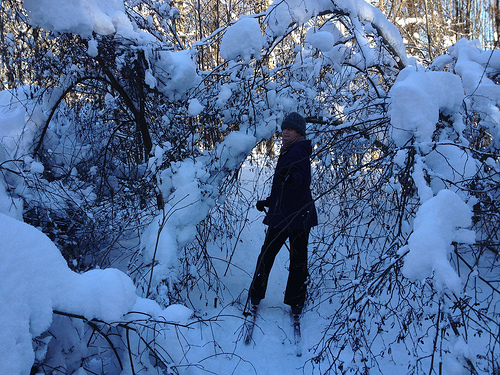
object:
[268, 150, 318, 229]
jacket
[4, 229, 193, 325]
snow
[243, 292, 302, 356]
skis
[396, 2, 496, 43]
sky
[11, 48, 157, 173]
branches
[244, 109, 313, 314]
woman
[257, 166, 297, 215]
gloves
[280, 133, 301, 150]
hair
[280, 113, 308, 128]
hat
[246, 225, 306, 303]
pants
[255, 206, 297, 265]
poles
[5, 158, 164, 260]
bushes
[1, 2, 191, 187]
tree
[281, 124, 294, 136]
head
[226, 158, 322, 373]
trail